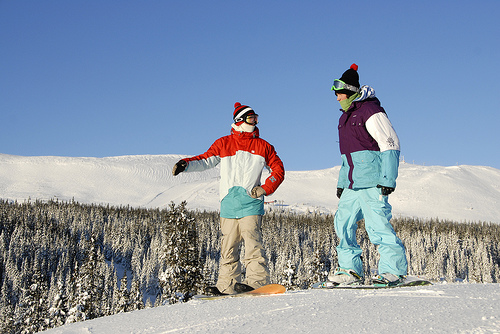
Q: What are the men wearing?
A: Parkas.